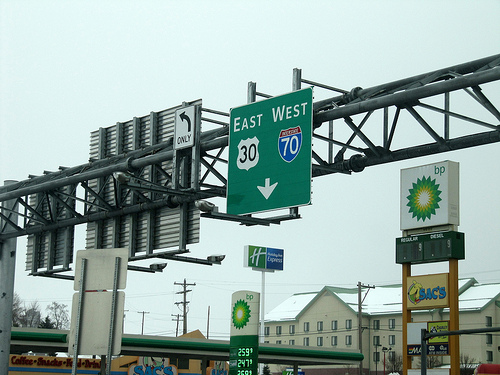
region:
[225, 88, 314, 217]
large green square sign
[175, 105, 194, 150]
white left turn only sign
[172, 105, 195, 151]
signis black and white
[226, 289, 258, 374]
bp gas price sign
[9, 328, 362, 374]
gas station is SAC'S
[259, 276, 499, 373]
hotel is Holiday Express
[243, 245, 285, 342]
tall Holiday Express billboard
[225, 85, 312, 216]
highway sign is over road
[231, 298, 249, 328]
green and yellow sun shape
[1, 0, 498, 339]
sky is grey and overcast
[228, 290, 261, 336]
the BP logo on a white background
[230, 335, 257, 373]
signs indicating gas prices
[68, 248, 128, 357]
the back of a traffic sign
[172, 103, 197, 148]
a left turn only sign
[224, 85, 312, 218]
sign indicating the way to the hightway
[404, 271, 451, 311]
a sign that says SAC'S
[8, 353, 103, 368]
red letters onthe side of the truck stop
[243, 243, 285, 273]
a Holiday Inn Express sign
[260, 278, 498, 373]
a hotel in he background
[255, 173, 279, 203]
a white arrow pointing down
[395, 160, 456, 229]
A green and yellow BP sign.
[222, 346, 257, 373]
A green sign displaying gas prices.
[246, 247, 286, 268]
A Holiday Inn Express sign.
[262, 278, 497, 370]
A large beige building.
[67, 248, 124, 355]
The backside of a street sign.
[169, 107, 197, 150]
A black and white road sign.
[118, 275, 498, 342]
Power lines.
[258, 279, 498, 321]
A roof with snow on it.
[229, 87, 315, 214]
A large green highway sign.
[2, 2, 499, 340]
A light grey colored sky.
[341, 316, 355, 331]
This is a window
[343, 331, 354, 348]
This is a window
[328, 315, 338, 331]
This is a window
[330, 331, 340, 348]
This is a window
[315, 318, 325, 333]
This is a window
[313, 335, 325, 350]
This is a window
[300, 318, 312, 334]
This is a window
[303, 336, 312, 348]
This is a window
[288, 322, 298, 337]
This is a window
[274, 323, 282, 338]
This is a window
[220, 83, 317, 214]
square green street sign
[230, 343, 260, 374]
prices of gas in green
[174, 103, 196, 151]
black and white street sign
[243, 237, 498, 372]
Holiday Inn Express hotel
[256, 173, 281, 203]
white arrow pointing down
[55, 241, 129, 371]
back of a street sign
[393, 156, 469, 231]
bp logo on a sign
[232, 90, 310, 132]
words east and west in white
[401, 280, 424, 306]
a yellow dog smiling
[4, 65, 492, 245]
metal beam holding street signs